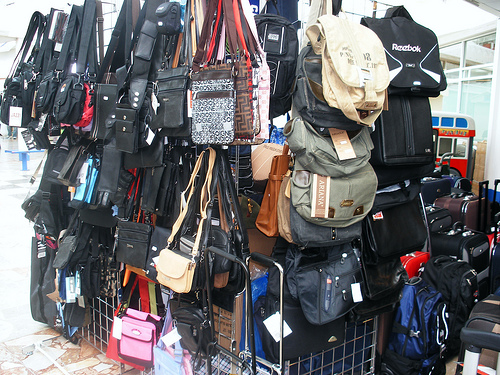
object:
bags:
[107, 216, 151, 271]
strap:
[161, 139, 217, 255]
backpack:
[381, 277, 452, 374]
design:
[190, 78, 235, 144]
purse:
[187, 0, 259, 148]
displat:
[256, 291, 347, 360]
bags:
[262, 286, 341, 356]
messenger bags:
[258, 287, 345, 354]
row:
[266, 1, 408, 344]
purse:
[109, 145, 174, 268]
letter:
[190, 78, 234, 143]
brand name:
[388, 41, 424, 54]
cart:
[201, 245, 286, 374]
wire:
[76, 295, 123, 353]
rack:
[77, 141, 376, 375]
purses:
[109, 1, 149, 158]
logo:
[327, 334, 338, 343]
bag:
[256, 300, 349, 360]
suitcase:
[401, 249, 431, 279]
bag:
[115, 308, 165, 369]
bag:
[276, 245, 369, 326]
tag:
[350, 282, 364, 303]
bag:
[355, 1, 449, 102]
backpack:
[305, 14, 397, 125]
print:
[288, 161, 378, 227]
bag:
[253, 149, 294, 237]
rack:
[254, 0, 380, 375]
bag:
[290, 155, 379, 227]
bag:
[290, 160, 378, 230]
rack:
[437, 33, 500, 114]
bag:
[190, 70, 236, 146]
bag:
[274, 155, 301, 245]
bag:
[374, 92, 438, 185]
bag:
[295, 41, 371, 132]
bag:
[365, 187, 422, 252]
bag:
[284, 110, 374, 178]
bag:
[165, 288, 218, 355]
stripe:
[313, 267, 342, 322]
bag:
[148, 145, 218, 296]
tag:
[261, 310, 292, 343]